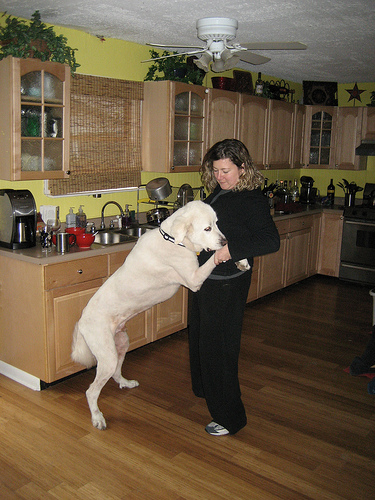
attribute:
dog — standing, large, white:
[73, 204, 222, 425]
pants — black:
[182, 288, 247, 426]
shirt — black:
[223, 195, 268, 252]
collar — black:
[156, 225, 179, 250]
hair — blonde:
[199, 138, 254, 170]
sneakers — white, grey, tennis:
[194, 410, 235, 437]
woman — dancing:
[198, 138, 271, 430]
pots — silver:
[153, 175, 171, 196]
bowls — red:
[73, 229, 98, 250]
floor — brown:
[284, 344, 329, 437]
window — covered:
[57, 62, 139, 187]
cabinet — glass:
[4, 57, 64, 174]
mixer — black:
[273, 183, 298, 212]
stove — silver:
[334, 226, 369, 284]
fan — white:
[172, 12, 302, 72]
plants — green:
[1, 16, 69, 64]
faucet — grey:
[86, 199, 134, 229]